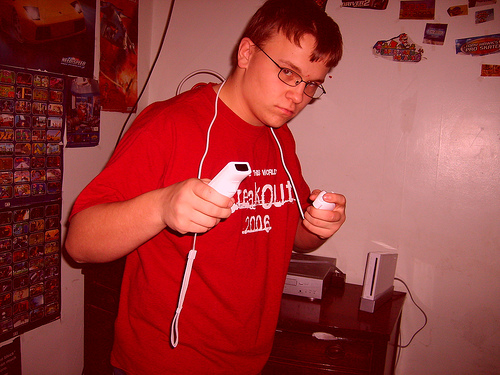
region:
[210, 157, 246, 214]
A Wii mote in his hand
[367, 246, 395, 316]
A nintendo Wii on a table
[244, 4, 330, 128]
A young man in glasses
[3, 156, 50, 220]
cards on the wall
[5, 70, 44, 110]
cards on the wall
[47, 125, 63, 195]
cards on the wall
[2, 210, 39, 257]
cards on the wall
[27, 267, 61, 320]
cards on the wall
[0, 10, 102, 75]
A poster on the wall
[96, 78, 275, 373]
A person in a red shirt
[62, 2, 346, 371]
boy in red shirt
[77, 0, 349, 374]
boy holding a video game remote control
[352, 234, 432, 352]
white video game system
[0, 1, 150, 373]
posters hanging on wall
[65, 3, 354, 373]
guy wearing glasses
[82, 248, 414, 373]
brown piece of furniture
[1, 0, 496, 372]
white walls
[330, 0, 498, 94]
video game related pictures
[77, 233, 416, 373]
dresser with electronics on top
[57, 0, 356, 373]
boy posing for picture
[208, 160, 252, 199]
A white wii remote.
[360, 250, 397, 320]
A wii game consol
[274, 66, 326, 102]
The man is wearing glasses.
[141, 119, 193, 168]
Part of a red shirt.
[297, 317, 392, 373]
Part of the dresser.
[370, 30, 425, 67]
A sticker on the wall.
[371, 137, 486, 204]
Part of the wall.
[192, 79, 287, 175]
A cord around the man's neck.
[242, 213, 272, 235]
The number 2006.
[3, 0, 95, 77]
A poster on the wall.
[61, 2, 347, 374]
man holding a remote control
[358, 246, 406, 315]
video game console on stand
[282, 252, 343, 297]
dvd player on stand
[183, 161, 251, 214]
video game remote control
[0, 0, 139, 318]
posters on white wall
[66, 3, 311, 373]
young man wearing glasses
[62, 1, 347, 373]
young man holding remote control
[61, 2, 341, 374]
young man wearing red shirt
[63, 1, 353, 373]
young man holding wiimote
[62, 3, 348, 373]
man holding wiimote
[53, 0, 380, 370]
man wears a red shirt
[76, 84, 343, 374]
red shirt has white letters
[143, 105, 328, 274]
white letters on a shirt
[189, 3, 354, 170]
man has short hair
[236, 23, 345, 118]
glasses on a face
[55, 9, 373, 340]
man holds game controls in both hands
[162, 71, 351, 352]
game control is white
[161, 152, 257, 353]
strap hangs from game control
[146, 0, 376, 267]
wire of game control around a neck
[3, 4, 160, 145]
posters on a wall